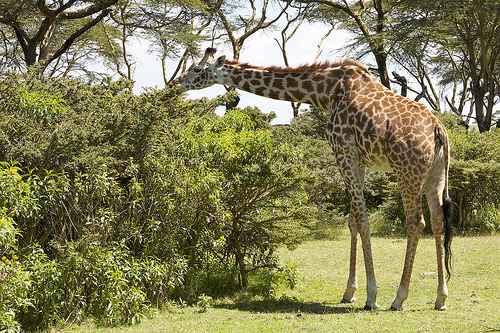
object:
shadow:
[208, 293, 365, 313]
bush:
[1, 64, 304, 331]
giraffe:
[170, 46, 454, 311]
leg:
[327, 130, 381, 309]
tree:
[3, 1, 127, 85]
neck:
[216, 60, 335, 107]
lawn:
[142, 208, 494, 322]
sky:
[2, 0, 474, 129]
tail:
[435, 123, 456, 283]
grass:
[102, 223, 490, 332]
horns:
[201, 46, 218, 60]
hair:
[227, 57, 357, 75]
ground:
[152, 225, 490, 332]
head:
[171, 50, 218, 90]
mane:
[222, 57, 373, 72]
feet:
[362, 300, 374, 307]